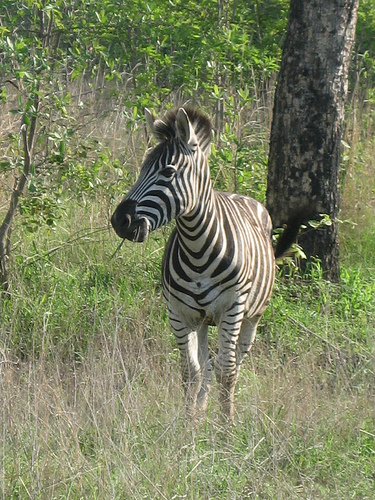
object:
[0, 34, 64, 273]
tree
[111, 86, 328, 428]
zebra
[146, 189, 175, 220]
stripe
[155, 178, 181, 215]
stripe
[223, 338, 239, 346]
stripe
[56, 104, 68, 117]
leaf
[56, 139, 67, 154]
leaf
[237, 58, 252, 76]
leaf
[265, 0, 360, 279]
tree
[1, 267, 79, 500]
grass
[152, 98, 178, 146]
hair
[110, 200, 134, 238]
snout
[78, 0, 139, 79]
foliage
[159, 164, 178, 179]
eye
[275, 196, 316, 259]
tail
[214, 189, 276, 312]
stripes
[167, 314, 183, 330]
stripe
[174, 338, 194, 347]
stripe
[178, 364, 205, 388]
knees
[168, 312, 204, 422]
leg